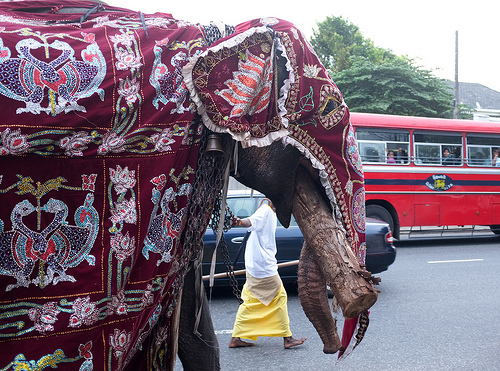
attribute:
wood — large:
[285, 172, 388, 312]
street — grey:
[172, 235, 498, 369]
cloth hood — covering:
[187, 15, 370, 364]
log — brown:
[296, 167, 377, 318]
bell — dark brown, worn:
[200, 128, 225, 158]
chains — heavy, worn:
[185, 124, 245, 307]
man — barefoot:
[256, 164, 338, 356]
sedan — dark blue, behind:
[197, 187, 400, 297]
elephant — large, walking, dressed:
[3, 3, 379, 369]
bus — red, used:
[346, 111, 498, 245]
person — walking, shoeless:
[222, 194, 312, 351]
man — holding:
[240, 199, 292, 355]